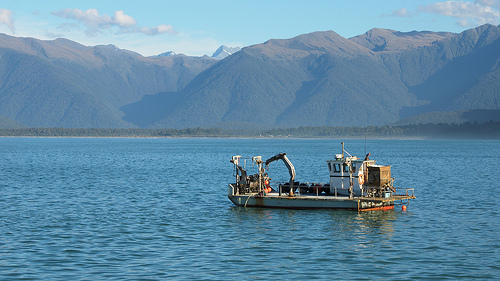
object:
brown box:
[363, 165, 391, 186]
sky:
[0, 0, 497, 42]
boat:
[228, 141, 417, 211]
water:
[5, 135, 498, 274]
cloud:
[0, 0, 498, 42]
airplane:
[228, 141, 416, 212]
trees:
[0, 120, 500, 139]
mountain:
[0, 22, 500, 129]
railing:
[279, 185, 337, 198]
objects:
[323, 185, 328, 193]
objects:
[309, 182, 317, 194]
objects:
[300, 182, 307, 191]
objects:
[281, 182, 299, 192]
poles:
[232, 154, 264, 194]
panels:
[237, 164, 257, 191]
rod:
[230, 155, 264, 196]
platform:
[363, 187, 413, 202]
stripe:
[359, 206, 395, 212]